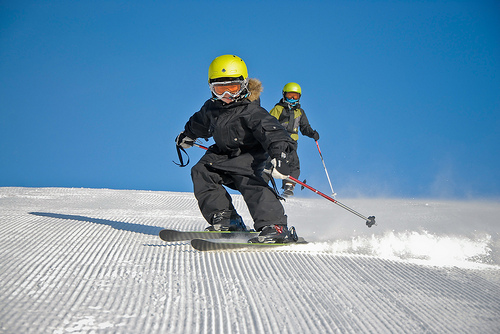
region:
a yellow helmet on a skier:
[204, 52, 250, 82]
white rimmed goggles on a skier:
[206, 77, 247, 95]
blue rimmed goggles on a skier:
[282, 89, 300, 103]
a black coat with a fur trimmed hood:
[181, 80, 287, 173]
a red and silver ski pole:
[268, 167, 379, 228]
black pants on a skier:
[187, 159, 288, 227]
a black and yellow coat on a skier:
[272, 102, 314, 144]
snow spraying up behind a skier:
[292, 225, 490, 267]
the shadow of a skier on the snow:
[29, 207, 165, 237]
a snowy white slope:
[0, 185, 498, 331]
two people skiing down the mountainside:
[165, 38, 345, 253]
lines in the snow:
[17, 180, 477, 322]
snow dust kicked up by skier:
[307, 218, 482, 269]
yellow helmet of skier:
[203, 50, 246, 78]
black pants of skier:
[183, 148, 282, 233]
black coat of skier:
[188, 98, 284, 168]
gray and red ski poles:
[192, 135, 371, 225]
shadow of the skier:
[25, 201, 170, 237]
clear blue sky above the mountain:
[7, 5, 487, 189]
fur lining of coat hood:
[250, 75, 260, 107]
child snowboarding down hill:
[155, 40, 350, 238]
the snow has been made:
[134, 16, 358, 272]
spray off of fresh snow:
[87, 14, 442, 323]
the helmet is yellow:
[148, 37, 404, 299]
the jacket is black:
[153, 9, 348, 272]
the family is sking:
[148, 38, 357, 292]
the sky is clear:
[126, 34, 395, 292]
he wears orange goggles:
[176, 27, 403, 283]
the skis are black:
[146, 27, 383, 253]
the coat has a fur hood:
[138, 41, 371, 267]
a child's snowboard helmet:
[200, 50, 249, 105]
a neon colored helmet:
[279, 80, 306, 98]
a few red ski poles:
[283, 136, 380, 238]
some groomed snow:
[9, 208, 148, 324]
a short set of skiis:
[161, 220, 308, 251]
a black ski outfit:
[168, 57, 296, 233]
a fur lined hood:
[241, 78, 263, 110]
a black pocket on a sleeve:
[263, 123, 289, 149]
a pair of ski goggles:
[204, 76, 248, 101]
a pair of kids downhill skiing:
[161, 47, 398, 259]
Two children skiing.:
[155, 51, 375, 244]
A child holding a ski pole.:
[263, 162, 374, 228]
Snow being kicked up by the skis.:
[271, 226, 492, 264]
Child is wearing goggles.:
[207, 78, 247, 98]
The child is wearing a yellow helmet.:
[205, 55, 245, 90]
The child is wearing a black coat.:
[180, 90, 290, 170]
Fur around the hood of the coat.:
[240, 76, 264, 106]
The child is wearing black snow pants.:
[188, 160, 288, 222]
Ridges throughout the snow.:
[1, 185, 497, 331]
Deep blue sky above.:
[0, 23, 497, 200]